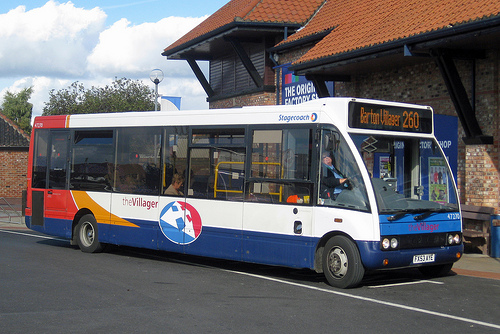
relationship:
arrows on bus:
[159, 200, 206, 245] [26, 96, 466, 288]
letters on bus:
[406, 221, 440, 232] [26, 96, 466, 288]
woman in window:
[166, 171, 186, 197] [164, 127, 186, 196]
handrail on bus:
[209, 159, 286, 201] [26, 96, 466, 288]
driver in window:
[320, 152, 353, 197] [312, 123, 372, 214]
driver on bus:
[320, 152, 353, 197] [26, 96, 466, 288]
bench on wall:
[462, 206, 497, 253] [459, 59, 499, 240]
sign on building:
[278, 63, 317, 103] [168, 6, 499, 104]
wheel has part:
[74, 214, 99, 252] [84, 225, 98, 251]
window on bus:
[354, 131, 457, 215] [26, 96, 466, 288]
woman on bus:
[166, 171, 186, 197] [26, 96, 466, 288]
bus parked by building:
[26, 96, 466, 288] [168, 6, 499, 104]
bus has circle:
[26, 96, 466, 288] [159, 200, 206, 245]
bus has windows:
[26, 96, 466, 288] [34, 127, 458, 208]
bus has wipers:
[26, 96, 466, 288] [390, 209, 446, 222]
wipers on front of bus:
[390, 209, 446, 222] [26, 96, 466, 288]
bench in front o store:
[462, 206, 497, 253] [170, 2, 499, 275]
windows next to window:
[34, 127, 458, 208] [343, 128, 463, 217]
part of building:
[367, 69, 424, 96] [168, 6, 499, 104]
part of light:
[155, 70, 162, 80] [148, 68, 161, 109]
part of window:
[171, 140, 181, 156] [164, 127, 186, 196]